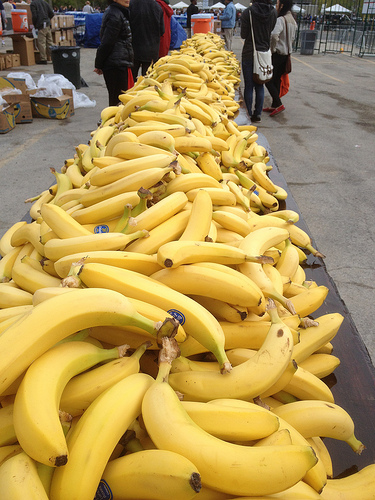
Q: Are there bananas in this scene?
A: Yes, there are bananas.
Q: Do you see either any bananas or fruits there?
A: Yes, there are bananas.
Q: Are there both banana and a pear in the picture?
A: No, there are bananas but no pears.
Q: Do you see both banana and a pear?
A: No, there are bananas but no pears.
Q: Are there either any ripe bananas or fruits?
A: Yes, there are ripe bananas.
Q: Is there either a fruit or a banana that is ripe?
A: Yes, the bananas are ripe.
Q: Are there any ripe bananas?
A: Yes, there are ripe bananas.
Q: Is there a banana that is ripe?
A: Yes, there are bananas that are ripe.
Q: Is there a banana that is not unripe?
A: Yes, there are ripe bananas.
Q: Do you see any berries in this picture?
A: No, there are no berries.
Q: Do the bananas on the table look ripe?
A: Yes, the bananas are ripe.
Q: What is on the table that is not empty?
A: The bananas are on the table.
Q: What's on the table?
A: The bananas are on the table.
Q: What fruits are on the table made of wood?
A: The fruits are bananas.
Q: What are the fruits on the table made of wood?
A: The fruits are bananas.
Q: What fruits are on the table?
A: The fruits are bananas.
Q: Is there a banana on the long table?
A: Yes, there are bananas on the table.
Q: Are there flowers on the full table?
A: No, there are bananas on the table.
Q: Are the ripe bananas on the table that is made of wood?
A: Yes, the bananas are on the table.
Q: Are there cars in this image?
A: No, there are no cars.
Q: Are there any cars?
A: No, there are no cars.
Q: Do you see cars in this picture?
A: No, there are no cars.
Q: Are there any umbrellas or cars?
A: No, there are no cars or umbrellas.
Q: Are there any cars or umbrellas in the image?
A: No, there are no cars or umbrellas.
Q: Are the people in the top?
A: Yes, the people are in the top of the image.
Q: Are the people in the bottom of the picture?
A: No, the people are in the top of the image.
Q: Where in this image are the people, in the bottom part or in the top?
A: The people are in the top of the image.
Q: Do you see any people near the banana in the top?
A: Yes, there are people near the banana.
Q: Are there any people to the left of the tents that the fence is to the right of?
A: Yes, there are people to the left of the tents.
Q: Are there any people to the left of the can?
A: No, the people are to the right of the can.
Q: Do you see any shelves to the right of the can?
A: No, there are people to the right of the can.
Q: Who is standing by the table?
A: The people are standing by the table.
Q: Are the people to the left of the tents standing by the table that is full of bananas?
A: Yes, the people are standing by the table.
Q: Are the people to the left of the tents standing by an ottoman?
A: No, the people are standing by the table.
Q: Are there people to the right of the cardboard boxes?
A: Yes, there are people to the right of the boxes.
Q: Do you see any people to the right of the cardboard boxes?
A: Yes, there are people to the right of the boxes.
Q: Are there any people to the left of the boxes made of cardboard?
A: No, the people are to the right of the boxes.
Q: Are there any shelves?
A: No, there are no shelves.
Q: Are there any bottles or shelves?
A: No, there are no shelves or bottles.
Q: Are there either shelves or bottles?
A: No, there are no shelves or bottles.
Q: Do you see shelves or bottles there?
A: No, there are no shelves or bottles.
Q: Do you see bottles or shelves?
A: No, there are no shelves or bottles.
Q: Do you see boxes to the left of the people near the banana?
A: Yes, there are boxes to the left of the people.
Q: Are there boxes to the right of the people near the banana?
A: No, the boxes are to the left of the people.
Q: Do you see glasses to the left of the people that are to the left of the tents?
A: No, there are boxes to the left of the people.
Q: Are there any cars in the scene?
A: No, there are no cars.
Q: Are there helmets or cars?
A: No, there are no cars or helmets.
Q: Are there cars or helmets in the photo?
A: No, there are no cars or helmets.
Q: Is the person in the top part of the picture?
A: Yes, the person is in the top of the image.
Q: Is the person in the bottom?
A: No, the person is in the top of the image.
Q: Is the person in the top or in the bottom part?
A: The person is in the top of the image.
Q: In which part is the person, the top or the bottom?
A: The person is in the top of the image.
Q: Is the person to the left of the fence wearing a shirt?
A: Yes, the person is wearing a shirt.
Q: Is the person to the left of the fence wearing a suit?
A: No, the person is wearing a shirt.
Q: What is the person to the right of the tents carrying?
A: The person is carrying a bag.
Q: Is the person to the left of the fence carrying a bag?
A: Yes, the person is carrying a bag.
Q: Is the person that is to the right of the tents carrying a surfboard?
A: No, the person is carrying a bag.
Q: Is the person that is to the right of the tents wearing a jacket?
A: Yes, the person is wearing a jacket.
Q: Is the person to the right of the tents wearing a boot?
A: No, the person is wearing a jacket.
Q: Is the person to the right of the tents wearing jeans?
A: Yes, the person is wearing jeans.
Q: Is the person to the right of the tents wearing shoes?
A: Yes, the person is wearing shoes.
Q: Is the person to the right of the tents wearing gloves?
A: No, the person is wearing shoes.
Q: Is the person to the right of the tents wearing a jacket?
A: Yes, the person is wearing a jacket.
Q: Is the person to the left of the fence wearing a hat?
A: No, the person is wearing a jacket.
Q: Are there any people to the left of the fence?
A: Yes, there is a person to the left of the fence.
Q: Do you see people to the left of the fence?
A: Yes, there is a person to the left of the fence.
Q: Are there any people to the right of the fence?
A: No, the person is to the left of the fence.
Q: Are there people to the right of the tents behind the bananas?
A: Yes, there is a person to the right of the tents.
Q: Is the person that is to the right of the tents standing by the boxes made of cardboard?
A: Yes, the person is standing by the boxes.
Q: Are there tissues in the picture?
A: No, there are no tissues.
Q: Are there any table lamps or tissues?
A: No, there are no tissues or table lamps.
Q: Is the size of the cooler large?
A: Yes, the cooler is large.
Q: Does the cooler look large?
A: Yes, the cooler is large.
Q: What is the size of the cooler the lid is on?
A: The cooler is large.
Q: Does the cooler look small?
A: No, the cooler is large.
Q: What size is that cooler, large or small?
A: The cooler is large.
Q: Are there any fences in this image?
A: Yes, there is a fence.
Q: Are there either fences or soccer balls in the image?
A: Yes, there is a fence.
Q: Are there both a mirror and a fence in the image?
A: No, there is a fence but no mirrors.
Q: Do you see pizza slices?
A: No, there are no pizza slices.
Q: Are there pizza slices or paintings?
A: No, there are no pizza slices or paintings.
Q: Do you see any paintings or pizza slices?
A: No, there are no pizza slices or paintings.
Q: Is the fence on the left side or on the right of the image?
A: The fence is on the right of the image.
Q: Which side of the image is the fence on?
A: The fence is on the right of the image.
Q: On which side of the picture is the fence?
A: The fence is on the right of the image.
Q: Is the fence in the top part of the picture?
A: Yes, the fence is in the top of the image.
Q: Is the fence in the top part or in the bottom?
A: The fence is in the top of the image.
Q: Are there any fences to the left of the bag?
A: No, the fence is to the right of the bag.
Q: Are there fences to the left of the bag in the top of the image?
A: No, the fence is to the right of the bag.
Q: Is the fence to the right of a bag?
A: Yes, the fence is to the right of a bag.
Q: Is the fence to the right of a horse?
A: No, the fence is to the right of a bag.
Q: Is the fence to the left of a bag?
A: No, the fence is to the right of a bag.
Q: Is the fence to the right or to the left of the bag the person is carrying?
A: The fence is to the right of the bag.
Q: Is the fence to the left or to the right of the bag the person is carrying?
A: The fence is to the right of the bag.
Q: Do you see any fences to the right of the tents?
A: Yes, there is a fence to the right of the tents.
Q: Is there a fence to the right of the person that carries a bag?
A: Yes, there is a fence to the right of the person.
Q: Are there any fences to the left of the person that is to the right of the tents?
A: No, the fence is to the right of the person.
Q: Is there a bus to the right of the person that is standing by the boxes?
A: No, there is a fence to the right of the person.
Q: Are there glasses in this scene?
A: No, there are no glasses.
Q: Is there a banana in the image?
A: Yes, there is a banana.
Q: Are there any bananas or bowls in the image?
A: Yes, there is a banana.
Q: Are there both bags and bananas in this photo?
A: Yes, there are both a banana and a bag.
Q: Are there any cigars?
A: No, there are no cigars.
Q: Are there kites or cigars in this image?
A: No, there are no cigars or kites.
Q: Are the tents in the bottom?
A: No, the tents are in the top of the image.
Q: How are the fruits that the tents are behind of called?
A: The fruits are bananas.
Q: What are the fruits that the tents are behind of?
A: The fruits are bananas.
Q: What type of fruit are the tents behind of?
A: The tents are behind the bananas.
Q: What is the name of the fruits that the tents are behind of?
A: The fruits are bananas.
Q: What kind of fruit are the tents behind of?
A: The tents are behind the bananas.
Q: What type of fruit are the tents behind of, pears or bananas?
A: The tents are behind bananas.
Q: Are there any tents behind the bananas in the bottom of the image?
A: Yes, there are tents behind the bananas.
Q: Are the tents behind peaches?
A: No, the tents are behind the bananas.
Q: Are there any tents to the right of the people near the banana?
A: Yes, there are tents to the right of the people.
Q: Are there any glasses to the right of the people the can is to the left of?
A: No, there are tents to the right of the people.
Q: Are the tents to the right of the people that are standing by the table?
A: Yes, the tents are to the right of the people.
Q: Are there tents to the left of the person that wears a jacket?
A: Yes, there are tents to the left of the person.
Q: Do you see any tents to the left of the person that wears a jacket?
A: Yes, there are tents to the left of the person.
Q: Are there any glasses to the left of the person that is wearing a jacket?
A: No, there are tents to the left of the person.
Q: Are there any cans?
A: Yes, there is a can.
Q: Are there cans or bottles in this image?
A: Yes, there is a can.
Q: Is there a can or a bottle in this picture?
A: Yes, there is a can.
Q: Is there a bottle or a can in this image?
A: Yes, there is a can.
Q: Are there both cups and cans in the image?
A: No, there is a can but no cups.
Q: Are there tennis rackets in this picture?
A: No, there are no tennis rackets.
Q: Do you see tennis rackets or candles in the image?
A: No, there are no tennis rackets or candles.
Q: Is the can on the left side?
A: Yes, the can is on the left of the image.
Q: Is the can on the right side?
A: No, the can is on the left of the image.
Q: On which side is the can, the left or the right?
A: The can is on the left of the image.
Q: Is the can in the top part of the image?
A: Yes, the can is in the top of the image.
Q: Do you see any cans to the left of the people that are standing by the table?
A: Yes, there is a can to the left of the people.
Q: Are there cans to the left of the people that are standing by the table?
A: Yes, there is a can to the left of the people.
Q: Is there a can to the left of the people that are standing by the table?
A: Yes, there is a can to the left of the people.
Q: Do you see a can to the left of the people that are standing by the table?
A: Yes, there is a can to the left of the people.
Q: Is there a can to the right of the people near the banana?
A: No, the can is to the left of the people.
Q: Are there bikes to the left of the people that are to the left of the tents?
A: No, there is a can to the left of the people.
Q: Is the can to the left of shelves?
A: No, the can is to the left of the people.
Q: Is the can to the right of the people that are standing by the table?
A: No, the can is to the left of the people.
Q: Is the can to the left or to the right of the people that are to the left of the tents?
A: The can is to the left of the people.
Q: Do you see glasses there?
A: No, there are no glasses.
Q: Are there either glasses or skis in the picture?
A: No, there are no glasses or skis.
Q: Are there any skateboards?
A: No, there are no skateboards.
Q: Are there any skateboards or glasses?
A: No, there are no skateboards or glasses.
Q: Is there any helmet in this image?
A: No, there are no helmets.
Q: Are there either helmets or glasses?
A: No, there are no helmets or glasses.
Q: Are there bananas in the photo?
A: Yes, there are bananas.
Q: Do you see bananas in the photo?
A: Yes, there are bananas.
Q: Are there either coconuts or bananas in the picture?
A: Yes, there are bananas.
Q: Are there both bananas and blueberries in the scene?
A: No, there are bananas but no blueberries.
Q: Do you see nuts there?
A: No, there are no nuts.